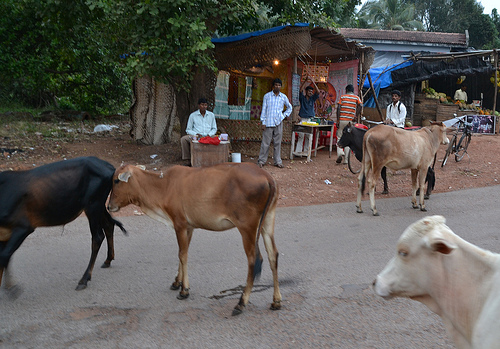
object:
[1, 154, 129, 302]
cow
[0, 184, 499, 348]
road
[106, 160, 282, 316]
cow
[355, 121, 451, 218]
cow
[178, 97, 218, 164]
man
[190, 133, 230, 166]
desk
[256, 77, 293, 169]
man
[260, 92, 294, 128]
shirt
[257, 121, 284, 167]
pants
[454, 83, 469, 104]
man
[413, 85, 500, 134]
stand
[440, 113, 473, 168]
bicycle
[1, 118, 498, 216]
ground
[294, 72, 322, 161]
person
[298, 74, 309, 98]
arm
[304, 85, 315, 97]
head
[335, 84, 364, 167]
man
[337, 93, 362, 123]
shirt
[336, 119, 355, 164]
pants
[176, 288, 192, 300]
hoof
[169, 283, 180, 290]
hoof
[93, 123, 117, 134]
garbage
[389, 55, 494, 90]
tarp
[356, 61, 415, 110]
tarp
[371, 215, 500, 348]
cow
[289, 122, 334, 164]
table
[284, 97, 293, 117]
arm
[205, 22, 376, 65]
roof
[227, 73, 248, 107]
window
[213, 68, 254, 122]
material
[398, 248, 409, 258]
eye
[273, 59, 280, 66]
light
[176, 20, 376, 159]
store